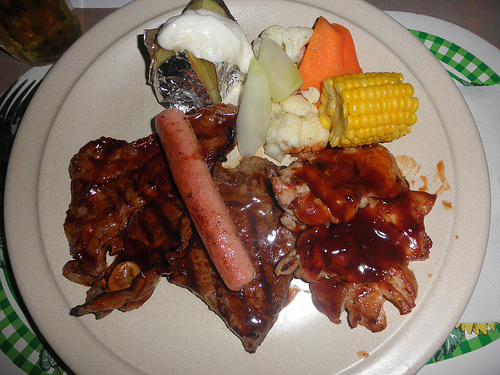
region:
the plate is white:
[259, 292, 396, 369]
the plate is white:
[285, 308, 370, 353]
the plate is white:
[273, 312, 347, 367]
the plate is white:
[242, 272, 332, 369]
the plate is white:
[263, 290, 313, 351]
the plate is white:
[273, 280, 318, 327]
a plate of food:
[23, 0, 493, 368]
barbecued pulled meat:
[282, 152, 427, 321]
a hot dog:
[154, 103, 261, 301]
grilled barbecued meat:
[65, 100, 296, 354]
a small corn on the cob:
[321, 67, 428, 149]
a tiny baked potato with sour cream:
[138, 6, 263, 111]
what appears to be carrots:
[293, 7, 373, 97]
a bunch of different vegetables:
[143, 5, 424, 154]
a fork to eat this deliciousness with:
[3, 68, 48, 340]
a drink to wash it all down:
[1, 2, 88, 75]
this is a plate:
[71, 87, 103, 117]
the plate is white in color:
[78, 80, 131, 121]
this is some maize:
[326, 70, 422, 139]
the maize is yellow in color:
[341, 82, 388, 120]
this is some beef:
[99, 165, 431, 270]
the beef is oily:
[281, 177, 378, 285]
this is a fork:
[1, 79, 41, 132]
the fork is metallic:
[5, 79, 45, 127]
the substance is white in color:
[168, 19, 216, 41]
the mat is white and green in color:
[443, 45, 458, 59]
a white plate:
[38, 10, 466, 373]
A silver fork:
[0, 50, 59, 168]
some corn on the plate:
[325, 70, 422, 153]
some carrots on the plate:
[315, 26, 368, 88]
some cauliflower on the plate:
[255, 17, 322, 170]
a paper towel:
[442, 75, 498, 317]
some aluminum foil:
[151, 2, 242, 108]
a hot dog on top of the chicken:
[151, 96, 273, 293]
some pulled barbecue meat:
[295, 142, 433, 337]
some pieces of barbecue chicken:
[70, 107, 282, 333]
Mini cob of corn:
[320, 73, 420, 144]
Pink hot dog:
[150, 108, 255, 289]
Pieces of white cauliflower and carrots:
[250, 14, 365, 157]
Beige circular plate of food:
[8, 0, 491, 370]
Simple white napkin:
[442, 81, 497, 329]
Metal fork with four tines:
[0, 75, 45, 336]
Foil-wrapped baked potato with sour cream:
[135, 8, 255, 110]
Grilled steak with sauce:
[71, 135, 292, 356]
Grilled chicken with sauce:
[277, 155, 447, 325]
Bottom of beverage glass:
[0, 0, 87, 68]